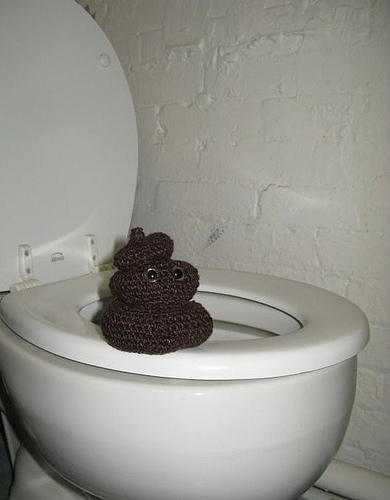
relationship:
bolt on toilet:
[26, 268, 30, 274] [2, 75, 385, 491]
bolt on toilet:
[91, 238, 97, 261] [2, 75, 385, 491]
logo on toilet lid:
[47, 252, 67, 264] [0, 0, 138, 295]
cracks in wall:
[133, 21, 354, 270] [82, 5, 388, 473]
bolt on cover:
[100, 52, 111, 67] [2, 3, 140, 292]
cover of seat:
[2, 3, 140, 292] [4, 80, 123, 230]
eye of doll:
[169, 261, 187, 287] [94, 208, 220, 361]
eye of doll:
[139, 263, 165, 292] [94, 208, 220, 361]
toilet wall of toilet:
[80, 0, 390, 500] [2, 1, 374, 431]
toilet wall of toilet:
[80, 0, 390, 500] [0, 0, 368, 498]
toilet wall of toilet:
[80, 0, 390, 500] [3, 219, 368, 494]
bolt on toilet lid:
[90, 237, 101, 264] [0, 0, 138, 295]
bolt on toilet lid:
[20, 243, 37, 260] [0, 0, 138, 295]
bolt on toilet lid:
[19, 268, 38, 280] [0, 0, 138, 295]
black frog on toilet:
[101, 227, 213, 356] [0, 0, 368, 498]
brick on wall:
[74, 0, 390, 482] [82, 5, 388, 473]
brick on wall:
[74, 0, 390, 482] [165, 5, 382, 230]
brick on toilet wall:
[74, 0, 390, 482] [80, 0, 390, 500]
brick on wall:
[74, 0, 390, 482] [128, 10, 378, 288]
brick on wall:
[204, 39, 295, 97] [82, 5, 388, 473]